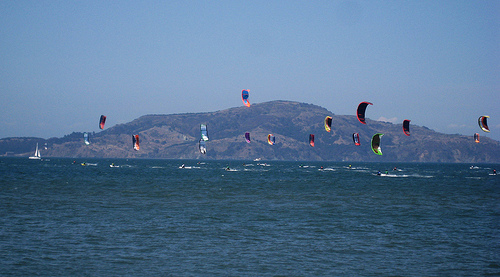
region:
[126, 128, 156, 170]
An orange and blue kite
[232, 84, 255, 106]
An orange and blue kite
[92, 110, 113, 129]
An orange and blue kite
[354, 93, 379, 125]
A red and black kite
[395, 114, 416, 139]
A red and black kite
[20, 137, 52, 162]
A white sea boat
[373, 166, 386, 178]
A person swimming in water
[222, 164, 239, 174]
A person swimming in water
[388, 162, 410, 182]
A person swimming in water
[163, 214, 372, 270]
A blue large water surface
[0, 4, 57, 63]
white clouds in blue sky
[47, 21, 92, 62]
white clouds in blue sky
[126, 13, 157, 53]
white clouds in blue sky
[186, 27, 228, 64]
white clouds in blue sky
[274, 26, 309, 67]
white clouds in blue sky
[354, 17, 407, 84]
white clouds in blue sky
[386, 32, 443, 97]
white clouds in blue sky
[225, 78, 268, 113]
large kite in sky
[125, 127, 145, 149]
large kite in sky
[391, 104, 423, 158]
large kite in sky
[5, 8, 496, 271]
picture taken outside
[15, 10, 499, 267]
picture taken during the day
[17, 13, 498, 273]
picture taken outdoors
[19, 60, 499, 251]
The mountain in the background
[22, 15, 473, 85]
the sky is void of clouds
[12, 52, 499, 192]
the people are on the ocean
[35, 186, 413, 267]
the ocean is calm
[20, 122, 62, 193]
a boat on the water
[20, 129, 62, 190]
the boat is sailing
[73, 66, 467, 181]
the sails are varied in colors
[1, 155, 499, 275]
Blue water under the kites.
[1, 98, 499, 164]
A large land mass in the distance.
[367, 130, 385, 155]
Black and green kite flying.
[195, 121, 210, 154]
Two blue and white kites one above the other.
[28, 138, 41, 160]
A white sailboat in the water.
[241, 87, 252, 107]
Orange and blue kite in the center sky.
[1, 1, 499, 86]
Blue sky from left to right above the kites.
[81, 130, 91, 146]
Blue and white kite close to the sailboat.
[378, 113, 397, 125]
Grey cloud to the right back of the large hill.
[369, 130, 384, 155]
Green and black kite flying over the water.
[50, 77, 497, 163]
kites over the sea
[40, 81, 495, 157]
kites are flying in the sky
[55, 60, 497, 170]
C-kites in the sky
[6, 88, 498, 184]
a mountain in front the sea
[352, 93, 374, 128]
kite is color red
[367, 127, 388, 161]
kite is color green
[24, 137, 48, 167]
a white boat in the sea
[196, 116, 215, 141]
a C-kite color blue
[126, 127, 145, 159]
a kite color blue, white and red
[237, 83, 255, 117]
an orange and blue kite